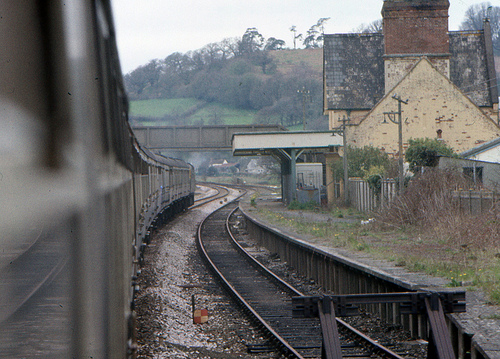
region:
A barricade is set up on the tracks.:
[287, 291, 475, 352]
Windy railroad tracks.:
[197, 220, 279, 307]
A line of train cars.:
[143, 140, 203, 222]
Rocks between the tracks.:
[151, 239, 212, 301]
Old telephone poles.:
[381, 93, 418, 166]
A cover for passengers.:
[228, 130, 345, 205]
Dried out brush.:
[372, 165, 498, 262]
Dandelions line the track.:
[258, 202, 385, 257]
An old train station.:
[326, 33, 488, 178]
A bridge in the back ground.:
[138, 119, 296, 151]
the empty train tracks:
[217, 203, 288, 331]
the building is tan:
[352, 53, 489, 168]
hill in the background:
[137, 83, 237, 125]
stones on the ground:
[137, 281, 202, 353]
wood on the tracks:
[222, 231, 277, 298]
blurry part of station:
[4, 155, 100, 301]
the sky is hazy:
[125, 3, 200, 43]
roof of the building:
[300, 38, 372, 103]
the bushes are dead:
[427, 219, 487, 246]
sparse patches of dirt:
[342, 228, 381, 258]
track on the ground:
[202, 189, 321, 338]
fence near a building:
[418, 179, 499, 217]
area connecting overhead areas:
[131, 112, 300, 153]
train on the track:
[5, 6, 197, 348]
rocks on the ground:
[164, 298, 191, 340]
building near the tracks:
[309, 5, 478, 151]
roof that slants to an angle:
[326, 34, 481, 99]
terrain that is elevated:
[131, 93, 261, 117]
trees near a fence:
[345, 133, 452, 181]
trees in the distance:
[127, 29, 326, 114]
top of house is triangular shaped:
[351, 55, 496, 154]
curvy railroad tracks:
[195, 179, 398, 357]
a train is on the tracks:
[3, 4, 195, 339]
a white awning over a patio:
[229, 130, 345, 152]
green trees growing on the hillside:
[123, 4, 495, 129]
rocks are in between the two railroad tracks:
[137, 178, 263, 353]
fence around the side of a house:
[443, 184, 495, 211]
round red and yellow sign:
[191, 305, 211, 325]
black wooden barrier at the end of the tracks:
[284, 284, 469, 352]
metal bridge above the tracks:
[131, 119, 291, 153]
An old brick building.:
[321, 0, 498, 174]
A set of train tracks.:
[191, 180, 405, 357]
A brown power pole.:
[384, 93, 411, 193]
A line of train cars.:
[1, 4, 198, 357]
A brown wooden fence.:
[347, 173, 399, 214]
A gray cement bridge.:
[131, 120, 287, 154]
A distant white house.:
[208, 157, 238, 173]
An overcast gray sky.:
[108, 2, 389, 75]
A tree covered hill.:
[125, 46, 329, 101]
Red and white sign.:
[191, 305, 208, 326]